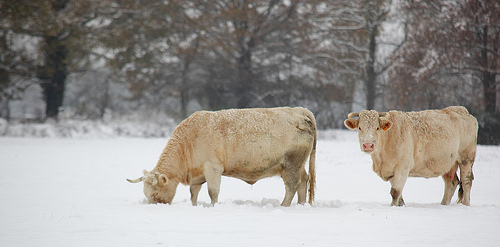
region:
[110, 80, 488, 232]
two cows are walking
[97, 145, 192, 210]
the cow`s face is in the snow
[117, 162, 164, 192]
the cow has horns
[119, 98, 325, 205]
the cow is white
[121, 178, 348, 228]
the snow is deep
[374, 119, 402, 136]
inside of the cows ear is pink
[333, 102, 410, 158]
the cow is looking at the camera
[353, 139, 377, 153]
the nose is pink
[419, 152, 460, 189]
the cow`s utter is pink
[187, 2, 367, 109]
the trees are bare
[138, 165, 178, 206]
Cow's nose is under snow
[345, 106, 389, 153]
Cow on right is staring at camera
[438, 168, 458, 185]
Cow has saggy pink udders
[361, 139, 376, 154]
Cow's nose is bright pink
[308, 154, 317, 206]
Cow's tail is long and shaggy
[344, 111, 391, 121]
Cow has two curly horns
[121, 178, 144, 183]
One of cow's horns is long and pointy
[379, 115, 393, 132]
Cow's left ear is big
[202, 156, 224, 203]
Cow has a very muscular left front leg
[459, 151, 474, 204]
Cow has patches of dark brown on it's left hind lef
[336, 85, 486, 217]
cow standing in snow covered field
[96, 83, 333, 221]
cow grazing in snow covered field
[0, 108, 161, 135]
row of bushes covered in snow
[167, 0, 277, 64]
tree with sparse brown leaves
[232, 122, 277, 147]
beige hair on side of cow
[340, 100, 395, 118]
white horns on head of cow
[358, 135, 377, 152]
pink cow nose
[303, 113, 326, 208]
large cow tail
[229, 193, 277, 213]
cow tracks in snow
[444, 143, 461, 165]
black spot on side of cow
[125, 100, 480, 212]
tan cows standing in show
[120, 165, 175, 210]
cow with face deep in snow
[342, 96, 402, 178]
bull with head turned to the left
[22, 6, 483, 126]
trees with gray branches and dark trunks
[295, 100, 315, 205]
tail hanging straight down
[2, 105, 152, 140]
foliage at tree base covered in snow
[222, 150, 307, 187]
black marks on belly and thighs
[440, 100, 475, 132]
flattened bump on rump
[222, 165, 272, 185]
bottom of belly coming to a point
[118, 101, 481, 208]
one cow standing behind the other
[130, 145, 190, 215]
brown cow grazing in snow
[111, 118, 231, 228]
brown cow grazing in snow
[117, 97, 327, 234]
brown cow grazing in snow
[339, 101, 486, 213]
brown cow in snow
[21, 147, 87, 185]
ground covered in white snow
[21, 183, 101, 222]
ground covered in white snow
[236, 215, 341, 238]
ground covered in white snow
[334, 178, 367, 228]
ground covered in white snow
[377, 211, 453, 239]
ground covered in white snow